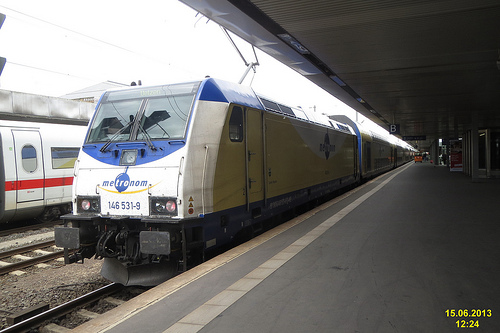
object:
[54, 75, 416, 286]
train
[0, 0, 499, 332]
station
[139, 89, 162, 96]
schedule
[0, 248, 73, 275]
tracks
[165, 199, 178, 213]
headlights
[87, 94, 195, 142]
windshield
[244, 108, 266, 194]
door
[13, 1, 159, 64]
sky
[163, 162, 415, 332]
line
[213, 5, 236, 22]
metal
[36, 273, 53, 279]
rock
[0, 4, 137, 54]
wire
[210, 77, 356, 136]
roof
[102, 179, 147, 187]
writing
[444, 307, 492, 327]
stamp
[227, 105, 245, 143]
window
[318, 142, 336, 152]
name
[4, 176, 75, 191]
stripe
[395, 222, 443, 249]
ground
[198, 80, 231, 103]
paint